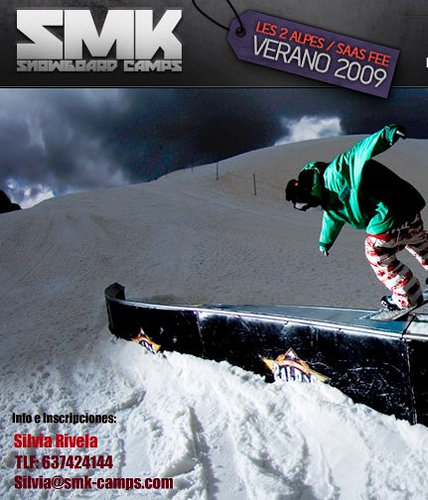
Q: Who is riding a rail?
A: Snowboarder.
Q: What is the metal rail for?
A: Snowboarding tricks.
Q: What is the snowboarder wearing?
A: Green jacket.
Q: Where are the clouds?
A: In the sky.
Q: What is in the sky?
A: Clouds.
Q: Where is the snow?
A: On the ground.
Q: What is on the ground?
A: Snow.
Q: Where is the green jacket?
A: On the man.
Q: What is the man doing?
A: Snowboarding.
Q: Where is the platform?
A: Under the man.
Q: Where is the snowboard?
A: Under the man.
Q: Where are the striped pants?
A: On the man's legs.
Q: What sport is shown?
A: Snowboarding.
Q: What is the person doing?
A: Snowboarding.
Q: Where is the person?
A: At a ski slope.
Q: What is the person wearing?
A: A coat.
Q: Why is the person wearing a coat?
A: It is cold.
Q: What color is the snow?
A: White.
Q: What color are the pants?
A: Red and White.